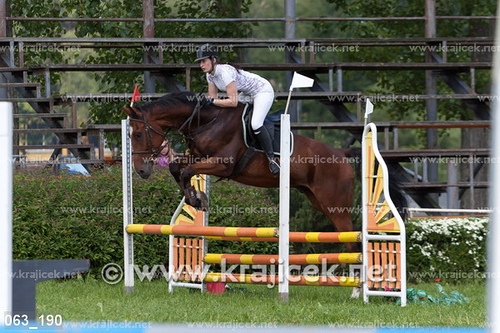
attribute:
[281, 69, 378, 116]
flags — white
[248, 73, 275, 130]
pants — white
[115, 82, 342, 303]
horse — brown, black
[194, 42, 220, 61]
helmet — black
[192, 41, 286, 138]
jockey — female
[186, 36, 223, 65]
helmet — strapped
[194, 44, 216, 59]
helmet — black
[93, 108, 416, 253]
horse — brown , black 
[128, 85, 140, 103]
flag — red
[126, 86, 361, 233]
horse — jumping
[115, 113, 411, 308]
poles — horizontal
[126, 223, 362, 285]
poles — orange, yellow